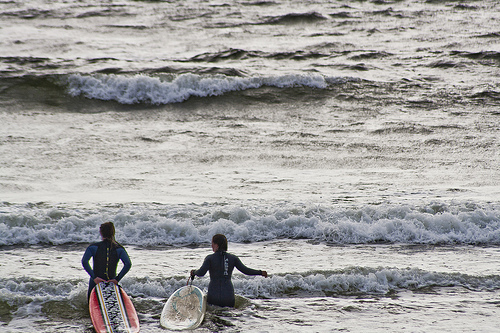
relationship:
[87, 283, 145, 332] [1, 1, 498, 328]
surfboard in water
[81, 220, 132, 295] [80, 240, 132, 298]
girl in wetsuit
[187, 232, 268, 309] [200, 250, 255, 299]
girl in wetsuit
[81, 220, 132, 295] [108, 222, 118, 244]
girl with ponytail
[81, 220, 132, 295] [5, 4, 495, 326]
girl in ocean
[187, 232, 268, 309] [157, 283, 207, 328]
girl dragging surfboard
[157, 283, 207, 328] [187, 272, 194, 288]
surfboard dragging by rope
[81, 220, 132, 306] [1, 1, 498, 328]
girl in water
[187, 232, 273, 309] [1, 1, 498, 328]
girl in water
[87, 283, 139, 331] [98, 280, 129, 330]
surfboard with stripe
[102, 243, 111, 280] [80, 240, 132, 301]
detailing on back of a wet suit